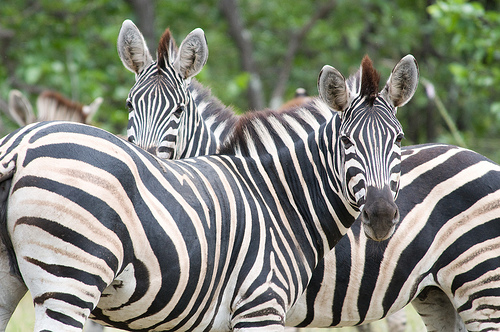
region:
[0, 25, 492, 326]
two striped zebras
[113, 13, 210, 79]
ears of a zebra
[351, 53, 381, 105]
a zebras mane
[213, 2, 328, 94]
a tree behind the zebras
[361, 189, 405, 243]
a zebras nose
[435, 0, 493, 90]
leaves on a tree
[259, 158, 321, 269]
zebra stripes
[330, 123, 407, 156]
a pair of zebra eyes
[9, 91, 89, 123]
the top of a zebras head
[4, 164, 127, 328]
the hind leg of a zebra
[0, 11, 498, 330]
Four zebras can be seen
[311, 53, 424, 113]
Pointy ears of zebra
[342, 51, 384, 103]
Mane of zebra is brown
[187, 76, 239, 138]
Mane of zebra is white and black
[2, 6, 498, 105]
Green trees in the background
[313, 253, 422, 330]
Belly of zebra is big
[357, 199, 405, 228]
Nostrils of zebra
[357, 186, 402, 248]
Muzzle of zebra is black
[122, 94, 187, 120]
Two eyes of zebra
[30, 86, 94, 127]
Mane border is brown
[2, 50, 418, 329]
A zebra looking at the camera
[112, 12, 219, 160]
Zebra standing behind another zebra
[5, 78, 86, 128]
Zebra ear and mane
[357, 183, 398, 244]
A zebra snout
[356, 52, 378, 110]
Front of a zebra mane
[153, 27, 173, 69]
Front of a zebra mane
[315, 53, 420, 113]
Zebra ears and mane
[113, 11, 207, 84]
Zebra ears and mane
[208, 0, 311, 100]
Blurred, lush tree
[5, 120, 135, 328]
A zebra's backside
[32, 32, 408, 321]
the zebras are looking at the camera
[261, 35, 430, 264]
the zebra is stripes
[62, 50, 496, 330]
the zebra is stripes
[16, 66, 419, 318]
the stripes are black and white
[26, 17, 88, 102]
the leaves are green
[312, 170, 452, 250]
the nose is black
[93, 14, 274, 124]
the ears are white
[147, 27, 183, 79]
the hair is brown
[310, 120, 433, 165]
the eyes are brown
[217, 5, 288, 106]
the branch is brown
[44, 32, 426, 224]
picture taken outdoors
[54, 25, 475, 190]
picture taken during the day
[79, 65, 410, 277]
the zebras are standing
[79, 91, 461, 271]
the zebras are black and white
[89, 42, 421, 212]
the zebras are looking at the camera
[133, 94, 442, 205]
the zebra has black eyes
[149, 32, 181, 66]
the zebra's mane is brown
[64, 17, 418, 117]
trees in the background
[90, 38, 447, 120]
the tree is full of leaves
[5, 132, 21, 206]
the tail of the zebra